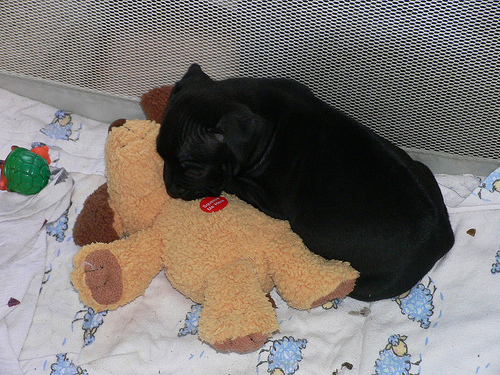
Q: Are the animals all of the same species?
A: No, there are both sheep and dogs.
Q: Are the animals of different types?
A: Yes, they are sheep and dogs.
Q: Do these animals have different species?
A: Yes, they are sheep and dogs.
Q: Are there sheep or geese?
A: Yes, there is a sheep.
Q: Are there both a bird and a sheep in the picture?
A: No, there is a sheep but no birds.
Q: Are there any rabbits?
A: No, there are no rabbits.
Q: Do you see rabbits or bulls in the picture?
A: No, there are no rabbits or bulls.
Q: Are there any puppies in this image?
A: Yes, there is a puppy.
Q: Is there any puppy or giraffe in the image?
A: Yes, there is a puppy.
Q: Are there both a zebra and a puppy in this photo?
A: No, there is a puppy but no zebras.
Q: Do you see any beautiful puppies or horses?
A: Yes, there is a beautiful puppy.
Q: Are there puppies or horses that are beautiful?
A: Yes, the puppy is beautiful.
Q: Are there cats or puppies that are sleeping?
A: Yes, the puppy is sleeping.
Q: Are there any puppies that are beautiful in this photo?
A: Yes, there is a beautiful puppy.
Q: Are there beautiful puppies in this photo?
A: Yes, there is a beautiful puppy.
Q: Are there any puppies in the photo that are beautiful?
A: Yes, there is a puppy that is beautiful.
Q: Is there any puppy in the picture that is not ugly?
A: Yes, there is an beautiful puppy.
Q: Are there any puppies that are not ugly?
A: Yes, there is an beautiful puppy.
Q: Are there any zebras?
A: No, there are no zebras.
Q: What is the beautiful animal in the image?
A: The animal is a puppy.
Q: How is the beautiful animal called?
A: The animal is a puppy.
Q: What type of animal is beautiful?
A: The animal is a puppy.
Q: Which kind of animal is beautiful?
A: The animal is a puppy.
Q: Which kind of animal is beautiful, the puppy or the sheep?
A: The puppy is beautiful.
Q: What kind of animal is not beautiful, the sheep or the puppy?
A: The sheep is not beautiful.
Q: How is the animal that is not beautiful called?
A: The animal is a sheep.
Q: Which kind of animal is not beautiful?
A: The animal is a sheep.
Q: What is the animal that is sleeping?
A: The animal is a puppy.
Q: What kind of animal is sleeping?
A: The animal is a puppy.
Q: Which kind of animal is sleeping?
A: The animal is a puppy.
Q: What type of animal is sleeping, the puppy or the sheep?
A: The puppy is sleeping.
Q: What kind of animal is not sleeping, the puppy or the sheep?
A: The sheep is not sleeping.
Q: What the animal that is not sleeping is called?
A: The animal is a sheep.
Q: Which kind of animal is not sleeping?
A: The animal is a sheep.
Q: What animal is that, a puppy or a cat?
A: That is a puppy.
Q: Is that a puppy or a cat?
A: That is a puppy.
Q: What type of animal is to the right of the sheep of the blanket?
A: The animal is a puppy.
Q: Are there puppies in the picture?
A: Yes, there is a puppy.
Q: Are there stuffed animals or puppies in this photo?
A: Yes, there is a puppy.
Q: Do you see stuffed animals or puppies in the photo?
A: Yes, there is a puppy.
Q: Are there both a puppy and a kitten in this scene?
A: No, there is a puppy but no kittens.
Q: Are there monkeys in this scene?
A: No, there are no monkeys.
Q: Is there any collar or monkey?
A: No, there are no monkeys or collars.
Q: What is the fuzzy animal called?
A: The animal is a puppy.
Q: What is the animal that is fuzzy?
A: The animal is a puppy.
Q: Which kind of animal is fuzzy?
A: The animal is a puppy.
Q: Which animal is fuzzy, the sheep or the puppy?
A: The puppy is fuzzy.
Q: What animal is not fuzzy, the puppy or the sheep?
A: The sheep is not fuzzy.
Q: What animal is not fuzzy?
A: The animal is a sheep.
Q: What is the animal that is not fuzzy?
A: The animal is a sheep.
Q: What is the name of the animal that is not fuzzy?
A: The animal is a sheep.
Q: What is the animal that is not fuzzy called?
A: The animal is a sheep.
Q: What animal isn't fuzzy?
A: The animal is a sheep.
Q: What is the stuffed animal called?
A: The animal is a puppy.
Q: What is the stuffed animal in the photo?
A: The animal is a puppy.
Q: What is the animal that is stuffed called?
A: The animal is a puppy.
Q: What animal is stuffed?
A: The animal is a puppy.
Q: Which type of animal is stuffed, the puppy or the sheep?
A: The puppy is stuffed.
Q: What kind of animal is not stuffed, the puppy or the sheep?
A: The sheep is not stuffed.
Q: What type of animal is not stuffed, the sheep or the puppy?
A: The sheep is not stuffed.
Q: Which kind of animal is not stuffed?
A: The animal is a sheep.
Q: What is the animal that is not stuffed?
A: The animal is a sheep.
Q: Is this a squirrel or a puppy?
A: This is a puppy.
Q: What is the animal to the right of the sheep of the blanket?
A: The animal is a puppy.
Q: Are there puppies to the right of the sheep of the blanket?
A: Yes, there is a puppy to the right of the sheep.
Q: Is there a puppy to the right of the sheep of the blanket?
A: Yes, there is a puppy to the right of the sheep.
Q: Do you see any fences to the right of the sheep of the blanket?
A: No, there is a puppy to the right of the sheep.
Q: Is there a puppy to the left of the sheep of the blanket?
A: Yes, there is a puppy to the left of the sheep.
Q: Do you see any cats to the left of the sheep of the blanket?
A: No, there is a puppy to the left of the sheep.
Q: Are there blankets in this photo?
A: Yes, there is a blanket.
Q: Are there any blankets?
A: Yes, there is a blanket.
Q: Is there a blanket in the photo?
A: Yes, there is a blanket.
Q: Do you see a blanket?
A: Yes, there is a blanket.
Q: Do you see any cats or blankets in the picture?
A: Yes, there is a blanket.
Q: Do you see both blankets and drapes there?
A: No, there is a blanket but no drapes.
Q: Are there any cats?
A: No, there are no cats.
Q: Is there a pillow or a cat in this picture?
A: No, there are no cats or pillows.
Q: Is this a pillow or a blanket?
A: This is a blanket.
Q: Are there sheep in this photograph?
A: Yes, there is a sheep.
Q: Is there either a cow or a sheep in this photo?
A: Yes, there is a sheep.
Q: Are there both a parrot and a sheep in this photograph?
A: No, there is a sheep but no parrots.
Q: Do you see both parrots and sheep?
A: No, there is a sheep but no parrots.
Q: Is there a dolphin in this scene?
A: No, there are no dolphins.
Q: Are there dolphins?
A: No, there are no dolphins.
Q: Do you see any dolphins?
A: No, there are no dolphins.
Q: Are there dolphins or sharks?
A: No, there are no dolphins or sharks.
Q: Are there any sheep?
A: Yes, there is a sheep.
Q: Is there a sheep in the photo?
A: Yes, there is a sheep.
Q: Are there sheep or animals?
A: Yes, there is a sheep.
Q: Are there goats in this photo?
A: No, there are no goats.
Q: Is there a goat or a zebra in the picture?
A: No, there are no goats or zebras.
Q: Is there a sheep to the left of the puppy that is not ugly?
A: Yes, there is a sheep to the left of the puppy.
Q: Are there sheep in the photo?
A: Yes, there is a sheep.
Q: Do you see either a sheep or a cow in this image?
A: Yes, there is a sheep.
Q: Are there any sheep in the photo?
A: Yes, there is a sheep.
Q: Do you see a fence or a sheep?
A: Yes, there is a sheep.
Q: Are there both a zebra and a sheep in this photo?
A: No, there is a sheep but no zebras.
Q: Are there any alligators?
A: No, there are no alligators.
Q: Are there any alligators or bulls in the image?
A: No, there are no alligators or bulls.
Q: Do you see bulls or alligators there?
A: No, there are no alligators or bulls.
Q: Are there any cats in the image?
A: No, there are no cats.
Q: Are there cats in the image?
A: No, there are no cats.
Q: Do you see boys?
A: No, there are no boys.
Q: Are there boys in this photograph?
A: No, there are no boys.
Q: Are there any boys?
A: No, there are no boys.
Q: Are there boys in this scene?
A: No, there are no boys.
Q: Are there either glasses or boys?
A: No, there are no boys or glasses.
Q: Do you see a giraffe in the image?
A: No, there are no giraffes.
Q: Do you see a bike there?
A: No, there are no bikes.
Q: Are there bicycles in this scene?
A: No, there are no bicycles.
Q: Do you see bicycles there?
A: No, there are no bicycles.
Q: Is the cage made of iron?
A: Yes, the cage is made of iron.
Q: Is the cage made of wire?
A: No, the cage is made of iron.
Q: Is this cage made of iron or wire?
A: The cage is made of iron.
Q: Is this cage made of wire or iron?
A: The cage is made of iron.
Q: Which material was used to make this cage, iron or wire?
A: The cage is made of iron.